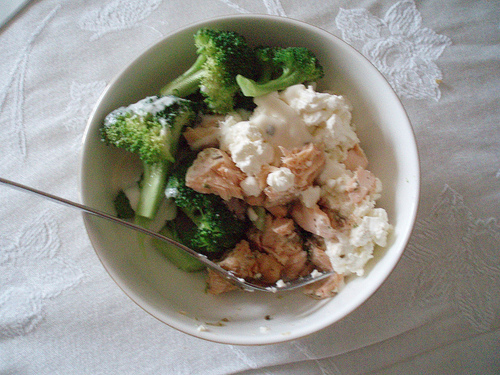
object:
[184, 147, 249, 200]
chicken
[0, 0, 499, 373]
table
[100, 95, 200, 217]
broccoli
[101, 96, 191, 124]
dressing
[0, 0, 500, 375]
linen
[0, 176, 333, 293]
fork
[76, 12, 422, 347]
bowl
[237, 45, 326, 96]
food